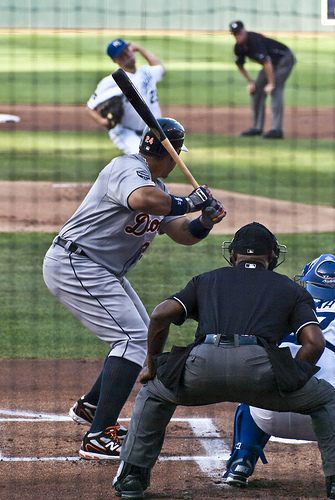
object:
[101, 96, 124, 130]
glove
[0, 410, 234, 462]
lines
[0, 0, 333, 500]
ground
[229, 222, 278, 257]
hat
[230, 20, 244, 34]
hat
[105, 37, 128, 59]
hat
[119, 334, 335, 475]
pants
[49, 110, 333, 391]
homebase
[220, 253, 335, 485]
catcher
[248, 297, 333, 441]
blue/white uniform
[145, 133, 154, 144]
number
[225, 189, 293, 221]
mound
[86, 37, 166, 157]
baseball player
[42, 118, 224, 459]
baseball player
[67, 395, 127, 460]
nike shoes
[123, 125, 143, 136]
belt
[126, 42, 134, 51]
ball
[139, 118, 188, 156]
blue helmet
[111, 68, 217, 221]
bat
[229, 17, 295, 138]
umpire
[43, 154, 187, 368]
grey uniform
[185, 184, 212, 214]
glove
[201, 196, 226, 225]
glove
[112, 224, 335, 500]
guy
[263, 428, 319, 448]
homeplate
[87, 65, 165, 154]
uniform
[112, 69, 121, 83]
end